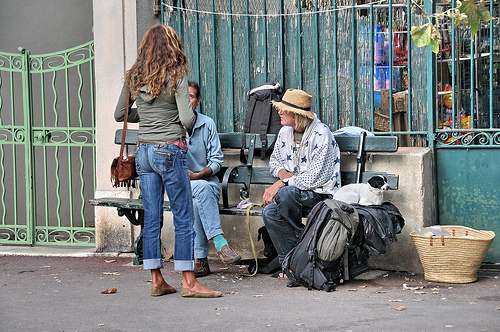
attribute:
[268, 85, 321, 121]
hat — straw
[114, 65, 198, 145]
hoodie — gray, green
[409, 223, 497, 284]
basket — tan, wicker, straw, woven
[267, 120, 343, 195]
longsleeve — white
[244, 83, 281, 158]
backpack — black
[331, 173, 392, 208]
dog — white, laying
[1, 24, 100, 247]
gate — green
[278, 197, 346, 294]
pack — black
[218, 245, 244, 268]
loafer — brown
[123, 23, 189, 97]
hair — long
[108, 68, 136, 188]
purse — suede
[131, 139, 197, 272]
jeans — blue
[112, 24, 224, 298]
woman — talking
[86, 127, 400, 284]
bench — wooden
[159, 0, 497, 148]
railing — teal